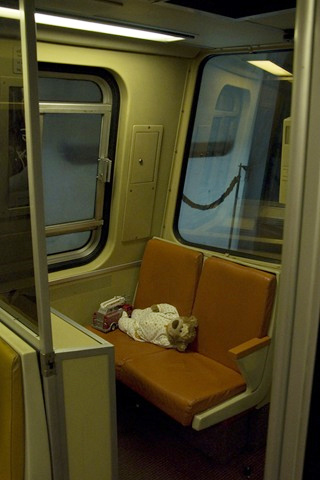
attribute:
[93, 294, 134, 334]
fire truck — red, small, toy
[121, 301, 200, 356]
bear — lying down, brown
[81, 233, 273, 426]
seat — brown, orange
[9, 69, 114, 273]
window — closed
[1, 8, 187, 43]
light — white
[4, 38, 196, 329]
wall — yellow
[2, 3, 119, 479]
trim — grey